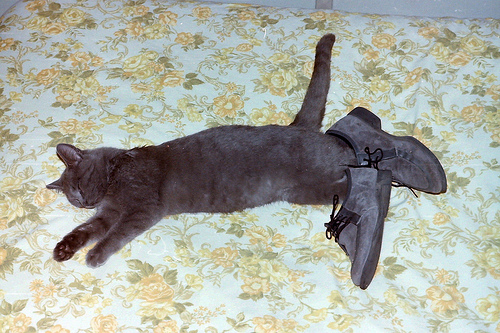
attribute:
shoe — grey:
[325, 171, 385, 287]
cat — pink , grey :
[40, 28, 358, 265]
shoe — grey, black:
[328, 160, 399, 292]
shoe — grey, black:
[335, 91, 455, 202]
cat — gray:
[30, 110, 307, 286]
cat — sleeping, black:
[37, 107, 385, 322]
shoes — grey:
[288, 88, 440, 281]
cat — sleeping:
[57, 120, 367, 259]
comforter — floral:
[15, 28, 445, 316]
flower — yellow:
[117, 46, 217, 106]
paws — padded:
[23, 230, 99, 286]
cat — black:
[45, 129, 330, 265]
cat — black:
[56, 100, 376, 285]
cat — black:
[27, 103, 298, 259]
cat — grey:
[24, 120, 292, 261]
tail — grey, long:
[280, 21, 383, 161]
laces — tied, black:
[318, 215, 372, 253]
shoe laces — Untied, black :
[366, 141, 381, 163]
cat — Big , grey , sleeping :
[39, 63, 369, 281]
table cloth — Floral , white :
[1, 2, 493, 323]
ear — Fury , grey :
[50, 136, 90, 168]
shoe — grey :
[327, 111, 452, 201]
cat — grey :
[14, 41, 352, 258]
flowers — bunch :
[121, 251, 185, 311]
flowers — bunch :
[232, 256, 272, 303]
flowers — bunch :
[400, 261, 485, 330]